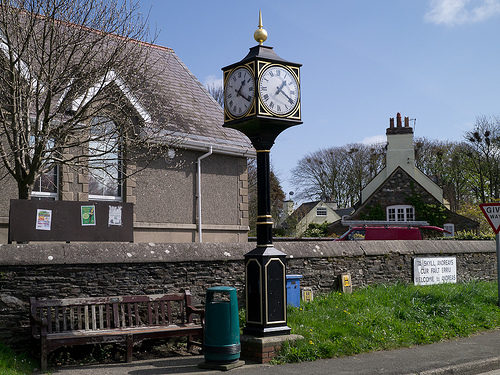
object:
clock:
[222, 63, 257, 118]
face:
[258, 62, 301, 116]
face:
[222, 65, 257, 119]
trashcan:
[201, 286, 241, 362]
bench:
[31, 287, 210, 368]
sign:
[412, 256, 457, 286]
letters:
[420, 267, 451, 275]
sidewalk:
[35, 328, 500, 375]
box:
[284, 274, 303, 309]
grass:
[238, 275, 499, 362]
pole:
[255, 148, 274, 247]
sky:
[1, 1, 500, 206]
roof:
[1, 9, 258, 159]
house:
[1, 4, 258, 245]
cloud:
[422, 0, 500, 27]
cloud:
[200, 75, 227, 95]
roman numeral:
[276, 70, 281, 76]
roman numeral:
[283, 74, 286, 79]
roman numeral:
[288, 81, 293, 85]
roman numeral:
[290, 90, 296, 95]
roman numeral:
[288, 99, 295, 105]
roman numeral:
[285, 104, 288, 109]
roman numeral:
[277, 105, 281, 111]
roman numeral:
[269, 101, 275, 108]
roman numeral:
[263, 93, 269, 101]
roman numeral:
[261, 86, 267, 91]